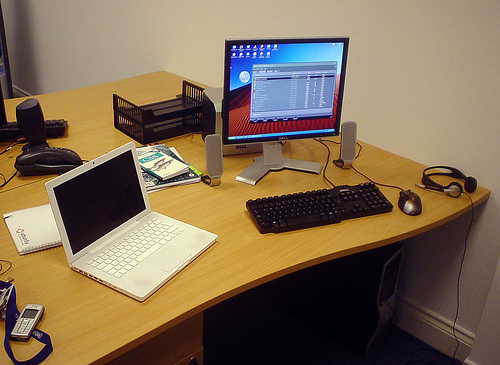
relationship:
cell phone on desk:
[11, 304, 46, 344] [0, 69, 485, 357]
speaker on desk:
[198, 130, 227, 190] [0, 69, 485, 357]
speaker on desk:
[332, 119, 362, 172] [0, 69, 485, 357]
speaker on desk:
[11, 95, 52, 155] [0, 69, 485, 357]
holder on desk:
[113, 79, 216, 145] [0, 69, 485, 357]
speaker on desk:
[332, 121, 358, 172] [0, 69, 485, 357]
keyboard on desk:
[238, 178, 395, 227] [0, 69, 485, 357]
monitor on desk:
[223, 37, 348, 138] [0, 69, 485, 357]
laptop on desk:
[42, 141, 217, 301] [0, 69, 485, 357]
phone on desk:
[12, 146, 88, 181] [0, 69, 485, 357]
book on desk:
[136, 148, 190, 182] [0, 69, 485, 357]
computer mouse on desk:
[396, 182, 425, 221] [0, 69, 485, 357]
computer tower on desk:
[328, 249, 403, 355] [198, 237, 303, 279]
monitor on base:
[223, 42, 343, 140] [236, 136, 325, 184]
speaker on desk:
[201, 133, 224, 186] [0, 69, 485, 357]